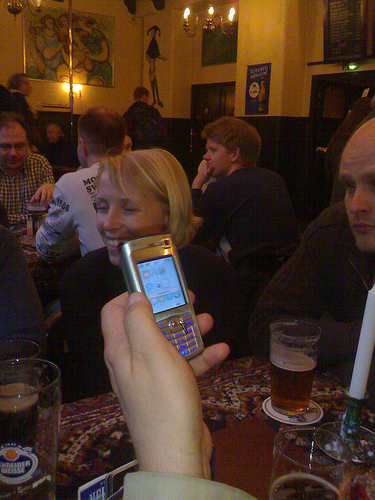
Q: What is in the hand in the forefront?
A: A phone.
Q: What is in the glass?
A: Beer.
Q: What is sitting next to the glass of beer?
A: A candlestick.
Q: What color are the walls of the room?
A: Yellow.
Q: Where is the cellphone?
A: In a hand.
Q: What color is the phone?
A: Silver.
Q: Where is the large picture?
A: On the wall.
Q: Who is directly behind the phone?
A: A blonde woman.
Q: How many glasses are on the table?
A: Three.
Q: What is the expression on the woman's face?
A: A smile.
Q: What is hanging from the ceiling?
A: Chandelier.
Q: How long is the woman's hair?
A: Shoulder length.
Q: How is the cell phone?
A: Turned on.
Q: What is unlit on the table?
A: Candle.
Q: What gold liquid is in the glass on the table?
A: Beer.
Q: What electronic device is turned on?
A: Phone.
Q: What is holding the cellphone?
A: Hand.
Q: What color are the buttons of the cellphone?
A: Blue.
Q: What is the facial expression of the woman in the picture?
A: Smile.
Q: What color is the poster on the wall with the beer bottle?
A: Blue.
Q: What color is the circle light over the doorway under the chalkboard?
A: Green.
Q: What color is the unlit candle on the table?
A: White.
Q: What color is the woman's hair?
A: Blonde.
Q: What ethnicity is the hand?
A: Caucasian.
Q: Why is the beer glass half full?
A: Someone drank some.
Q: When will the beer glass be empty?
A: Soon.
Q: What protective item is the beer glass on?
A: Coaster.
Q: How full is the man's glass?
A: Half.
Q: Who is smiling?
A: The blonde woman.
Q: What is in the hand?
A: Cell phone.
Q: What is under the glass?
A: Coaster.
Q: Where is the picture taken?
A: Restaurant.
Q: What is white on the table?
A: Candle.